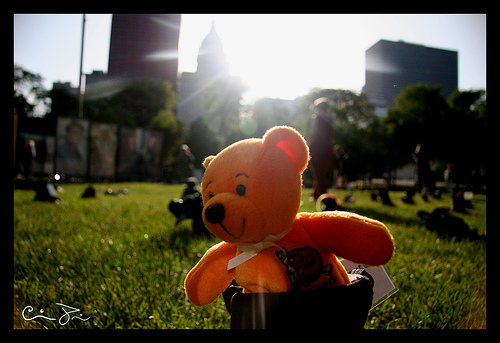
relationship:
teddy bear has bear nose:
[179, 117, 392, 341] [205, 203, 226, 224]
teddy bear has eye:
[179, 117, 392, 341] [229, 176, 246, 198]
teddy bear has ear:
[179, 117, 392, 341] [256, 117, 314, 179]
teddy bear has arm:
[179, 117, 392, 341] [284, 205, 401, 261]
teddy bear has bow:
[179, 117, 392, 341] [224, 234, 288, 270]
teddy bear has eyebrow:
[185, 126, 394, 306] [226, 161, 257, 179]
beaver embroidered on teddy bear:
[275, 233, 358, 313] [185, 126, 394, 306]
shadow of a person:
[406, 190, 486, 286] [462, 207, 498, 269]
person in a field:
[462, 207, 498, 269] [39, 164, 464, 339]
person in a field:
[301, 84, 344, 229] [43, 124, 448, 337]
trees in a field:
[305, 61, 497, 253] [39, 164, 464, 339]